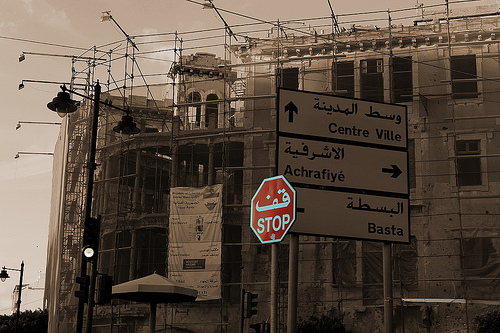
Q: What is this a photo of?
A: A building.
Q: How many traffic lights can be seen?
A: 1.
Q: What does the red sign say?
A: It says stop.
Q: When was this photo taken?
A: During the day.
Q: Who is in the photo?
A: Nobody.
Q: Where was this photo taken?
A: In an Arabic speaking country.